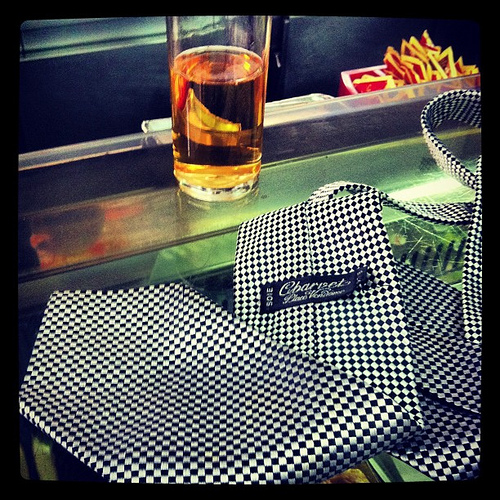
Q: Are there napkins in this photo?
A: No, there are no napkins.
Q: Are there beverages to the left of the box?
A: Yes, there is a beverage to the left of the box.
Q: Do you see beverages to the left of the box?
A: Yes, there is a beverage to the left of the box.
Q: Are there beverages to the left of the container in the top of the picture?
A: Yes, there is a beverage to the left of the box.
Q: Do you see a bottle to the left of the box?
A: No, there is a beverage to the left of the box.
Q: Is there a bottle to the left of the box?
A: No, there is a beverage to the left of the box.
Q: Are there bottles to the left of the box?
A: No, there is a beverage to the left of the box.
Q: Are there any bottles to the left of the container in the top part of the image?
A: No, there is a beverage to the left of the box.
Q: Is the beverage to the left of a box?
A: Yes, the beverage is to the left of a box.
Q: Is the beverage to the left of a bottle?
A: No, the beverage is to the left of a box.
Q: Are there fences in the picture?
A: No, there are no fences.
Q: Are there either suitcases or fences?
A: No, there are no fences or suitcases.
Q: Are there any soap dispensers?
A: No, there are no soap dispensers.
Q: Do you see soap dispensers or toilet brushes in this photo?
A: No, there are no soap dispensers or toilet brushes.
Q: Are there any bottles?
A: No, there are no bottles.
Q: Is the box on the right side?
A: Yes, the box is on the right of the image.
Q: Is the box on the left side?
A: No, the box is on the right of the image.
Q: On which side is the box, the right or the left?
A: The box is on the right of the image.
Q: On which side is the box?
A: The box is on the right of the image.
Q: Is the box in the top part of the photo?
A: Yes, the box is in the top of the image.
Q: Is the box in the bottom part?
A: No, the box is in the top of the image.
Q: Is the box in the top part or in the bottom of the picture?
A: The box is in the top of the image.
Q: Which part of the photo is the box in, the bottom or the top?
A: The box is in the top of the image.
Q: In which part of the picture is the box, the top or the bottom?
A: The box is in the top of the image.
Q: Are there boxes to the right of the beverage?
A: Yes, there is a box to the right of the beverage.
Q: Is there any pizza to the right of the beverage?
A: No, there is a box to the right of the beverage.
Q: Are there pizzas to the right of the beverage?
A: No, there is a box to the right of the beverage.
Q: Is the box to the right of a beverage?
A: Yes, the box is to the right of a beverage.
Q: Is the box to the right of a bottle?
A: No, the box is to the right of a beverage.